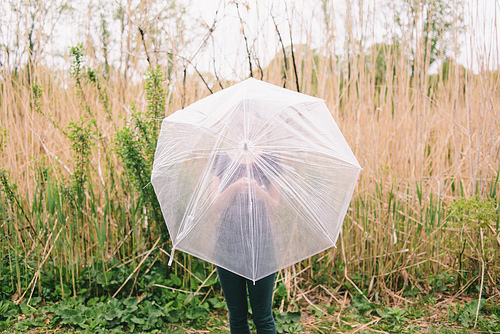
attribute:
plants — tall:
[13, 52, 468, 272]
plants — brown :
[371, 87, 462, 193]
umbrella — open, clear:
[150, 75, 358, 294]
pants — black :
[209, 231, 282, 322]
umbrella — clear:
[142, 77, 369, 288]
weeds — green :
[55, 126, 156, 270]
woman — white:
[214, 95, 280, 329]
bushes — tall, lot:
[25, 88, 146, 298]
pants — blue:
[214, 281, 269, 330]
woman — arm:
[205, 79, 316, 300]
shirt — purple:
[197, 159, 278, 212]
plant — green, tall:
[66, 27, 155, 304]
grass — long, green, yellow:
[362, 111, 469, 289]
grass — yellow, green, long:
[386, 138, 470, 280]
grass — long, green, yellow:
[380, 90, 480, 295]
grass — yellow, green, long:
[378, 96, 483, 326]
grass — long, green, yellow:
[393, 100, 463, 306]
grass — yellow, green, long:
[409, 94, 484, 294]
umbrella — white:
[166, 73, 345, 282]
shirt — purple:
[206, 145, 295, 238]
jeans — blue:
[217, 270, 269, 330]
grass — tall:
[418, 194, 484, 297]